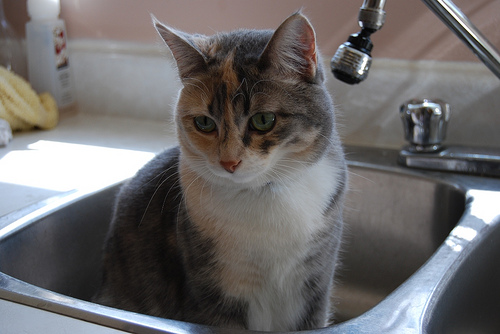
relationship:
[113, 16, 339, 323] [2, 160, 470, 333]
cat in sink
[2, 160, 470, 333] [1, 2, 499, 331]
sink in kitchen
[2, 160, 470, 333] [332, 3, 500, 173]
sink has faucet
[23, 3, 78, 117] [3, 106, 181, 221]
bottle on counter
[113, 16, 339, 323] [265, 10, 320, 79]
cat has ear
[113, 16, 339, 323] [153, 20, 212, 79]
cat has ear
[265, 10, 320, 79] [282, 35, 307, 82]
ear has hair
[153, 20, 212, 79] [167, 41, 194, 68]
ear has hair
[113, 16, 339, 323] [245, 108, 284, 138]
cat has eye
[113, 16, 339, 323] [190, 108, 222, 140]
cat has eye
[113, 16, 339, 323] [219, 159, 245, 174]
cat has nose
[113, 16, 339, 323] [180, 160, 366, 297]
cat has chest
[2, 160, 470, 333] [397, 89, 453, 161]
sink has knob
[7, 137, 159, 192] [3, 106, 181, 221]
sunshine on counter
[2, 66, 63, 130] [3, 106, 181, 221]
towel on counter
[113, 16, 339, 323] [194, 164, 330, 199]
cat has neck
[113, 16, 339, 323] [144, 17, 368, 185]
cat has head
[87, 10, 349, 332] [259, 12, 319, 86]
cat right ear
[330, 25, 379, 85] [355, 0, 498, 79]
water spout on faucet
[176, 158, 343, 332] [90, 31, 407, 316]
patch on cat